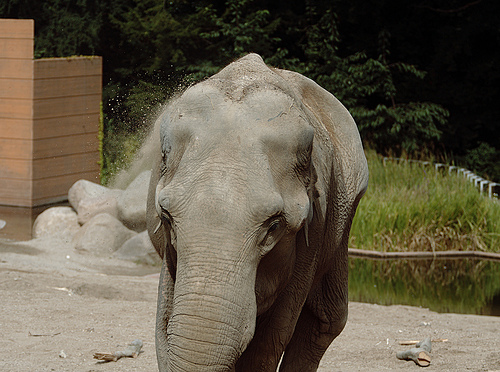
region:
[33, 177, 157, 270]
a stack of small boulders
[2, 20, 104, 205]
concrete or cinder block walls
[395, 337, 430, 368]
an object laying on the ground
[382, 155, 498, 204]
fence posts in the background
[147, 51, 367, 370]
an elephant facing the camera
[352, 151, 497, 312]
tall grass behind the elephant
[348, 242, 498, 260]
a limb laying horizontally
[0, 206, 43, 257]
a puddle of water by the wall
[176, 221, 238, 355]
the rough skin of an elephant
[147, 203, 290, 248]
the eyes of the elephant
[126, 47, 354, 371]
Grey elephant looking at the camera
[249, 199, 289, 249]
Elephant's eye is sunken in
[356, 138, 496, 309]
Green grass behind elephant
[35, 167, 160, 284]
Pile of large rocks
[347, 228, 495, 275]
Dead tree lying on the ground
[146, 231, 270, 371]
Elephant's trunk has wrinkles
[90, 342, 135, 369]
Wooden stick lying on the ground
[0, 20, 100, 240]
The brown built structure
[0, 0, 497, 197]
The thick background vegetation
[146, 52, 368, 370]
A gray tusk-less elephant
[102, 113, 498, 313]
The overgrown background grass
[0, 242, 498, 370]
The gray surface dirt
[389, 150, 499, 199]
A low fence on the right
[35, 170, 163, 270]
Pieces of gray rocks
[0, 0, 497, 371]
A lone elephant in a zoo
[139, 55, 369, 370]
The malnourished pale elephant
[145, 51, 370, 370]
The elephant is facing the camera.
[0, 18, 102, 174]
A wall is in the background.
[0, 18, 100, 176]
The wall is made of wood.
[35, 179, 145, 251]
Rocks are in the background.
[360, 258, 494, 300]
Water is in the background.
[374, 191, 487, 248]
Grass is behind the water.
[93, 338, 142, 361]
A stick is on the ground.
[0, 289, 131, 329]
The ground is sandy.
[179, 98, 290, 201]
The elephant is grey.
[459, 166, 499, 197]
A fence is in the background.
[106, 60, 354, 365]
this is an elephant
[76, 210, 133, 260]
this is a rock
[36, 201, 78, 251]
this is a rock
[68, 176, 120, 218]
this is a rock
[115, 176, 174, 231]
this is a rock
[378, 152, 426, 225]
this is grass on the side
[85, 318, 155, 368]
this is a piece of wood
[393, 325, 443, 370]
this is a piece of wood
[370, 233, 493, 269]
this is a piece of wood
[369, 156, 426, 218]
this is grass on the side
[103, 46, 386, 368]
Elephant in the dirt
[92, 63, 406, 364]
Large elephant in the dirt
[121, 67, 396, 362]
Big elephant in the dirt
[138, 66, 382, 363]
Large gray elephant in the dirt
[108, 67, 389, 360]
Gray elephant in the dirt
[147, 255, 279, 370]
Large trunk on elephant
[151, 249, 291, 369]
Large gray trunk on elephant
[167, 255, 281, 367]
Large trunk on gray elephant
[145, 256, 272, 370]
Trunk on large gray elephant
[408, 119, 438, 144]
green leaves on the tree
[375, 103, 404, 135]
green leaves on the tree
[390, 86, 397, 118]
green leaves on the tree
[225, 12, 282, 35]
green leaves on the tree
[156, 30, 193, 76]
green leaves on the tree